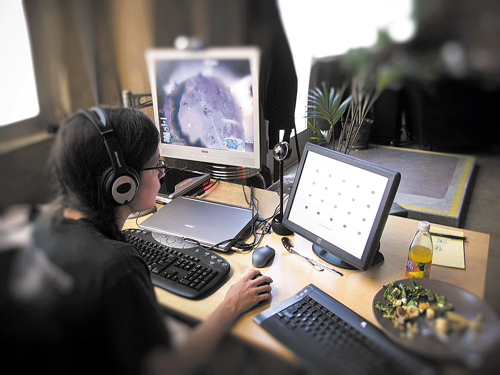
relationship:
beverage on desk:
[381, 225, 435, 289] [104, 116, 474, 346]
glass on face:
[115, 151, 171, 206] [106, 133, 192, 229]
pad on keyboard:
[183, 235, 223, 293] [107, 204, 251, 320]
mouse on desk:
[236, 235, 285, 274] [104, 116, 474, 346]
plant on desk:
[249, 78, 355, 214] [104, 116, 474, 346]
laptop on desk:
[124, 162, 262, 282] [104, 116, 474, 346]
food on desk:
[366, 260, 492, 348] [104, 116, 474, 346]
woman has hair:
[0, 50, 256, 360] [68, 131, 101, 174]